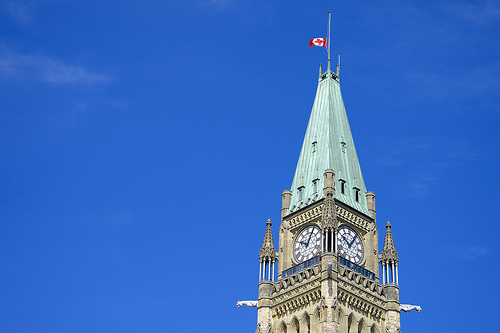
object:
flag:
[308, 37, 327, 48]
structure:
[236, 71, 421, 333]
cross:
[315, 38, 324, 44]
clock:
[292, 225, 322, 263]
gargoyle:
[400, 304, 422, 312]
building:
[236, 12, 422, 333]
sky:
[0, 0, 500, 333]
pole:
[327, 11, 331, 71]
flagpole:
[327, 13, 331, 70]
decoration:
[259, 264, 400, 320]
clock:
[337, 226, 364, 264]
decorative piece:
[236, 299, 258, 307]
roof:
[284, 78, 376, 219]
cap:
[283, 77, 374, 219]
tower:
[234, 77, 423, 333]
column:
[381, 253, 401, 333]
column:
[256, 249, 274, 333]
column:
[321, 222, 338, 332]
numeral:
[307, 228, 310, 233]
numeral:
[315, 231, 320, 236]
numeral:
[316, 236, 321, 241]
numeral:
[315, 245, 320, 249]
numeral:
[311, 252, 315, 256]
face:
[293, 224, 322, 263]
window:
[346, 311, 355, 333]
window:
[357, 318, 366, 333]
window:
[369, 322, 378, 333]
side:
[327, 198, 421, 333]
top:
[276, 50, 379, 280]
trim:
[272, 261, 322, 317]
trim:
[337, 264, 386, 320]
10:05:
[295, 225, 315, 246]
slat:
[328, 12, 332, 71]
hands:
[300, 241, 310, 245]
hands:
[306, 226, 316, 248]